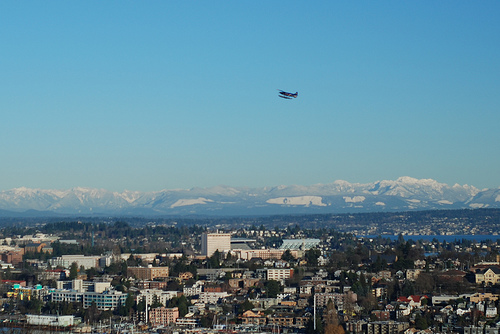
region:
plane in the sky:
[272, 85, 312, 109]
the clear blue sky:
[0, 0, 499, 81]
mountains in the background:
[0, 188, 160, 216]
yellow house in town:
[478, 267, 499, 284]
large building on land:
[53, 288, 125, 310]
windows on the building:
[268, 269, 282, 279]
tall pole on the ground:
[307, 296, 322, 327]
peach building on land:
[150, 307, 179, 322]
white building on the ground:
[30, 311, 73, 327]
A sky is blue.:
[1, 0, 496, 191]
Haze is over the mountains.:
[3, 147, 493, 191]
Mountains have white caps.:
[0, 175, 485, 208]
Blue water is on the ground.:
[351, 232, 498, 241]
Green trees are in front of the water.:
[385, 231, 490, 253]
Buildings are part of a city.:
[1, 230, 498, 332]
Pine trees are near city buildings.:
[41, 215, 326, 240]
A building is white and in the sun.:
[201, 232, 230, 250]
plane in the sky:
[274, 79, 304, 106]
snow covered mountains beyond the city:
[291, 175, 433, 214]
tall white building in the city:
[202, 224, 234, 261]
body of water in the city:
[391, 228, 466, 245]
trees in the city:
[331, 246, 376, 268]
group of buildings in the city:
[352, 322, 400, 332]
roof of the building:
[278, 236, 322, 250]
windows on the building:
[96, 296, 108, 304]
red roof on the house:
[408, 293, 420, 303]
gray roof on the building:
[28, 241, 38, 247]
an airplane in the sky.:
[275, 83, 301, 103]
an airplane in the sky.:
[276, 87, 296, 100]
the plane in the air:
[270, 78, 302, 109]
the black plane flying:
[275, 79, 308, 111]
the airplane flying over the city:
[270, 82, 299, 107]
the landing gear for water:
[275, 93, 294, 102]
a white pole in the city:
[310, 292, 319, 333]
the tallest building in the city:
[200, 230, 232, 262]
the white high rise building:
[202, 231, 232, 260]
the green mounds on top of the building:
[10, 280, 44, 294]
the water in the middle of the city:
[373, 229, 498, 244]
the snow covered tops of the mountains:
[8, 174, 498, 216]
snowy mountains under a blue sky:
[1, 3, 499, 215]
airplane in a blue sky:
[1, 1, 499, 187]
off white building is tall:
[200, 228, 231, 258]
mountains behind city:
[1, 177, 497, 332]